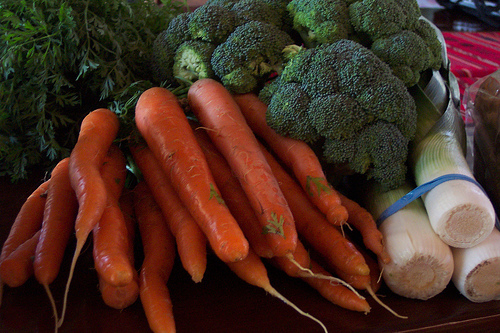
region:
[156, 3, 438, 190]
broccoli florets on a table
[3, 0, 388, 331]
a bunch of carrots on a table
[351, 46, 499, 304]
three leeks on a table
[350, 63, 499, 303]
leeks are tied together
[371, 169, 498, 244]
a blue band around some leeks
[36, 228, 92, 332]
skinny root ends of two carrots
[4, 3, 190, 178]
green carrot tops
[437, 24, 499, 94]
a dark pink patterned table cloth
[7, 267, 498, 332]
wooden surface under some vegetables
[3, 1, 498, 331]
fresh vegetables are displayed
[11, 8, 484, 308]
some vegetables sit on the table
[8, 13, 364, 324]
some carrots are on the table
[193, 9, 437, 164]
some broccoli is on the table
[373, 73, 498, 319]
a few leeks lay on the table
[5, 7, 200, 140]
the tops of carrots have leaves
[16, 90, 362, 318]
the carrots are orange in color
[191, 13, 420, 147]
the broccoli is green in color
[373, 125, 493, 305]
the leeks are white and green in color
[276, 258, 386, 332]
a few carrots still have roots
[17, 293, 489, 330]
the surface the vegetables sit on is made of wood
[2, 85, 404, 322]
Orange carrots on the table.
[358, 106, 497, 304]
Leeks on the table.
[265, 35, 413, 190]
Broccoli on the table.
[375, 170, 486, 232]
blue rubber band around the leeks.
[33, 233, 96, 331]
roots on the carrots.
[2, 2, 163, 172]
Green leafy vegetable in the back.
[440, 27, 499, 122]
Table cloth in the background.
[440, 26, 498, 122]
Stripes on the tablecloth.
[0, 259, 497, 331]
wooden table in the forefront.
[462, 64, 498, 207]
Loaf of bread on the table.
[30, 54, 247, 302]
orange carrots in pile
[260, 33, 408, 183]
pile of green broccoli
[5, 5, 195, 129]
green and leafy vegetable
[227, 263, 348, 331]
orange strings on carrots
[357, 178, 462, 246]
blue band on onions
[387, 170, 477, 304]
white ends of onions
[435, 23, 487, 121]
red cloth behind vegetables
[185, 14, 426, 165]
broccoli is dark green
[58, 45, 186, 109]
green stems on carrots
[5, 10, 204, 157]
green herbs behind carrots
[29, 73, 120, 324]
carrot on a table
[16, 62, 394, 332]
bunch of carrots on a table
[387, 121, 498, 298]
onions on top of table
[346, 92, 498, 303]
bunch of onions on a table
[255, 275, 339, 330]
root of a carrot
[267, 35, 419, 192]
broccoli on a table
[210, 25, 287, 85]
broccoli on a table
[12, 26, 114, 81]
spinach on a table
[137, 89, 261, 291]
carrot on a table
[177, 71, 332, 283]
carrot on a table